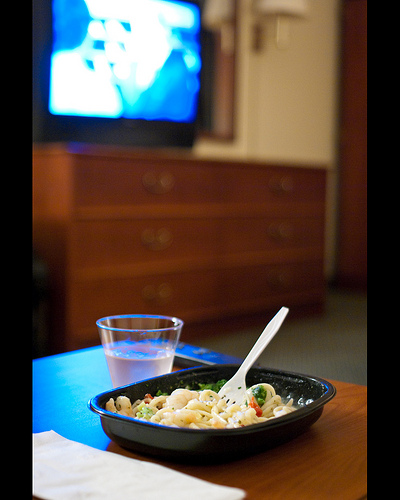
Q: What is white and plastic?
A: Fork.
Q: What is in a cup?
A: Water.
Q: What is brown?
A: Dresser.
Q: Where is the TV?
A: On dresser.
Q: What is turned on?
A: TV screen.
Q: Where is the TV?
A: On a dresser.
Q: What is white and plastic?
A: Fork.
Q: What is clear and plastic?
A: Cup.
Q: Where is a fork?
A: In a container.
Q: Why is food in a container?
A: To be eaten.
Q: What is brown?
A: Dresser.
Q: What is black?
A: Food container.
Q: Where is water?
A: In a cup.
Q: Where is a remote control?
A: On the table.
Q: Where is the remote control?
A: Behind the cup.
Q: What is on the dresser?
A: A television.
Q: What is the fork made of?
A: Plastic.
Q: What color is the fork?
A: White.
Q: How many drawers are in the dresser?
A: Six.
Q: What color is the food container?
A: Black.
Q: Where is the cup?
A: On the table.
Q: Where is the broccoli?
A: Mixed in the pasta.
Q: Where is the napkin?
A: On the Table.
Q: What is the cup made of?
A: Clear plastic.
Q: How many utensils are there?
A: 1.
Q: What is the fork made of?
A: Plastic.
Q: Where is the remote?
A: On the table.